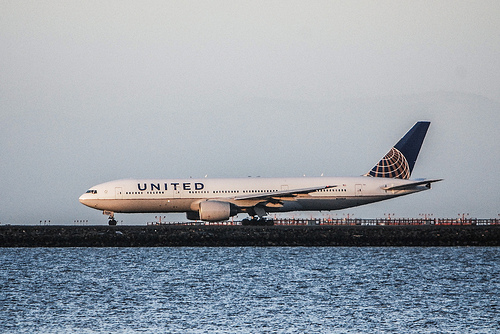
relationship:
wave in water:
[218, 256, 310, 310] [9, 234, 498, 332]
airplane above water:
[9, 246, 456, 333] [9, 228, 490, 322]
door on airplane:
[115, 187, 122, 197] [76, 120, 444, 226]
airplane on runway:
[76, 120, 444, 226] [3, 221, 498, 233]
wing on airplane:
[231, 180, 336, 202] [35, 101, 477, 247]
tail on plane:
[363, 118, 442, 196] [71, 110, 453, 240]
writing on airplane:
[134, 182, 207, 192] [68, 114, 451, 231]